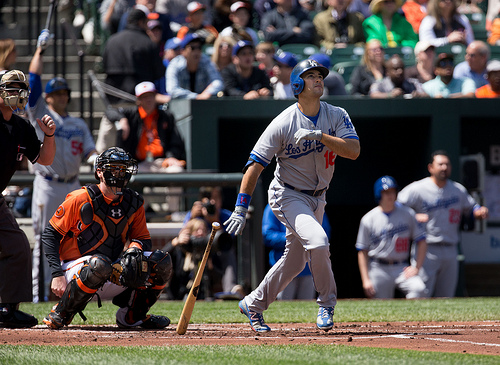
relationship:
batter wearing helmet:
[220, 56, 362, 336] [288, 56, 329, 97]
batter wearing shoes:
[220, 56, 362, 336] [234, 294, 345, 337]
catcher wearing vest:
[39, 145, 175, 333] [75, 183, 146, 263]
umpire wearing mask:
[3, 66, 58, 333] [2, 70, 35, 115]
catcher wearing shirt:
[39, 145, 175, 333] [42, 186, 154, 281]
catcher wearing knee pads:
[39, 145, 175, 333] [77, 249, 173, 291]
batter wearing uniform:
[220, 56, 362, 336] [239, 103, 355, 312]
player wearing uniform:
[352, 175, 429, 302] [355, 206, 429, 300]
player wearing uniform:
[397, 150, 487, 300] [394, 176, 480, 297]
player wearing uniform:
[27, 26, 100, 306] [24, 73, 94, 304]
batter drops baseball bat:
[220, 56, 362, 336] [175, 220, 224, 334]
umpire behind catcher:
[3, 66, 58, 333] [39, 145, 175, 333]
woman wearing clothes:
[361, 1, 422, 53] [361, 16, 422, 52]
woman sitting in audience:
[361, 1, 422, 53] [66, 1, 499, 98]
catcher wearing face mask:
[39, 145, 175, 333] [92, 146, 138, 192]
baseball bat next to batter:
[175, 220, 224, 334] [220, 56, 362, 336]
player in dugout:
[352, 175, 429, 302] [191, 99, 497, 298]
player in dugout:
[397, 150, 487, 300] [191, 99, 497, 298]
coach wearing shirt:
[116, 82, 191, 223] [131, 104, 169, 159]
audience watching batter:
[66, 1, 499, 98] [220, 56, 362, 336]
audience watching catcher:
[66, 1, 499, 98] [39, 145, 175, 333]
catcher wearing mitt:
[39, 145, 175, 333] [117, 246, 154, 295]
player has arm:
[27, 26, 100, 306] [23, 28, 59, 123]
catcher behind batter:
[39, 145, 175, 333] [220, 56, 362, 336]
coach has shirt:
[116, 82, 191, 223] [131, 104, 169, 159]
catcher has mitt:
[39, 145, 175, 333] [117, 246, 154, 295]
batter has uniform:
[220, 56, 362, 336] [239, 103, 355, 312]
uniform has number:
[239, 103, 355, 312] [317, 146, 339, 179]